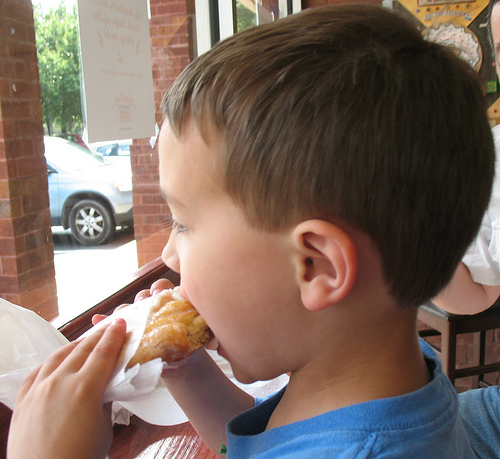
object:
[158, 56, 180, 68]
red brick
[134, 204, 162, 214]
brick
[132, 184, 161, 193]
brick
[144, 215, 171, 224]
brick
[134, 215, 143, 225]
brick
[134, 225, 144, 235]
brick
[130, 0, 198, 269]
beam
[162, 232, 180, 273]
nose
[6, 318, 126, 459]
hand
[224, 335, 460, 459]
t-shirt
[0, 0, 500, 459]
restaurant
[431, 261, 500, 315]
elbow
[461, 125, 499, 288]
shirt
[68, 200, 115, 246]
front tire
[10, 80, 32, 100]
brick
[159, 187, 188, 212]
eyebrow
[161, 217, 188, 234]
eye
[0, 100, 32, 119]
brick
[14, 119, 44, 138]
brick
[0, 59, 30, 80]
brick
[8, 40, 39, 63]
brick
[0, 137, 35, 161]
brick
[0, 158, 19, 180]
bricks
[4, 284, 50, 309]
bricks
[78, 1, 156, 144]
column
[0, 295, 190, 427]
waxed paper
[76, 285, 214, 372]
food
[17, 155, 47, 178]
brick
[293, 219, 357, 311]
ear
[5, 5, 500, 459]
boy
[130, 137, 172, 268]
crabrick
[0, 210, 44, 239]
bricks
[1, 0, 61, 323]
beam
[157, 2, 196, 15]
brick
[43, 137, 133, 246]
car